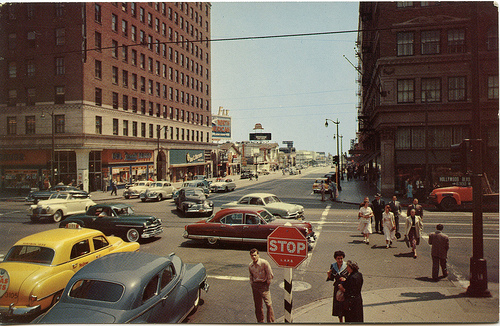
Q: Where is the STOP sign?
A: On the corner.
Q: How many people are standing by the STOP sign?
A: Three.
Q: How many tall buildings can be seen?
A: Two.